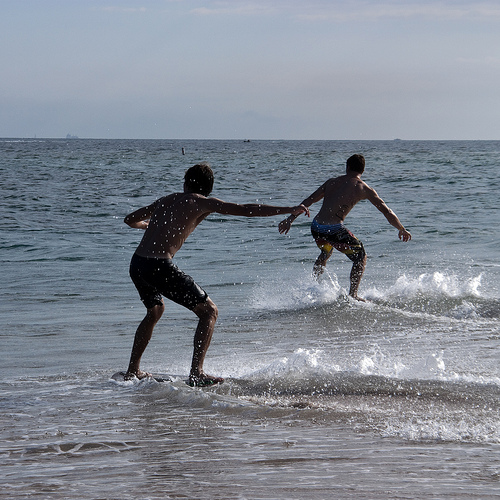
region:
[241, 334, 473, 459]
nice waves in the ocean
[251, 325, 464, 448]
good waves in the ocean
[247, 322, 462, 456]
small waves in the ocean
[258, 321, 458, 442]
beautiful waves in the ocean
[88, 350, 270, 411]
two feet on surfboard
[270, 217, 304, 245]
left hand of a person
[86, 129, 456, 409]
two people are in water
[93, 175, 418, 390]
they are looking in the same direction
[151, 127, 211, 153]
a person in the middle of the ocean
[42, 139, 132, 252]
the water i s calm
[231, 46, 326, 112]
sky is coverd of clouds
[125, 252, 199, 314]
shorts are black in color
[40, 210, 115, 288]
water is blue in color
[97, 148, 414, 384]
two people surfing in ocean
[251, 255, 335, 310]
white water splash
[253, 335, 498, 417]
water wave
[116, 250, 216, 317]
pair of black shorts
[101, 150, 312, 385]
man standing on surfboard with arms outstretched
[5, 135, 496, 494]
body of water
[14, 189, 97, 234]
dark line ripples in water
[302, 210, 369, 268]
blue and black shorts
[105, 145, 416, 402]
Two surfers surfing the ocean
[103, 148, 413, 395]
Two surfers surfing the ocean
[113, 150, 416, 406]
Two surfers surfing the ocean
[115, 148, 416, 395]
Two surfers surfing the ocean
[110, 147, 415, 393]
Two surfers surfing the ocean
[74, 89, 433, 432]
people surfing the waves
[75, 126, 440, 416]
two people surfing the waves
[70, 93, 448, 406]
couple people surfing the waves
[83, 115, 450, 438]
male people surfing the waves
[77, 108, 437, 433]
people surfing the ocean waves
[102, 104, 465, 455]
people surfing the calm waves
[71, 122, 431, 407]
people surfing the nice waves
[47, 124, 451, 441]
people surfing the water waves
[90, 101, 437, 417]
people surfing the awesome waves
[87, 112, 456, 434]
two people surfing some waves